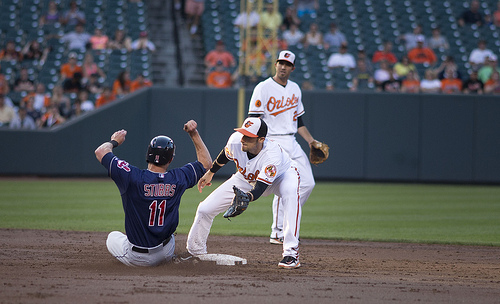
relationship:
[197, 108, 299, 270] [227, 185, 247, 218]
man wearing glove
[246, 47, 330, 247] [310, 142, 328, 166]
man wearing glove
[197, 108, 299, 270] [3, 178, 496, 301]
man on field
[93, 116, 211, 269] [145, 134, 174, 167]
man wearing helmet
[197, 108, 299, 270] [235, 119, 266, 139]
man wearing hat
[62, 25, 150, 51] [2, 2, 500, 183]
spectators sitting in stands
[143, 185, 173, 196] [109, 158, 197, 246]
name on jersey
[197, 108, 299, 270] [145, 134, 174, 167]
man wearing helmet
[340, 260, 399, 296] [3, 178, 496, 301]
tracks on field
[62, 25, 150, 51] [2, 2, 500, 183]
spectators in stands